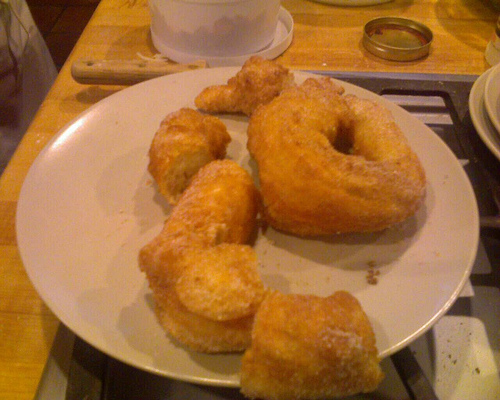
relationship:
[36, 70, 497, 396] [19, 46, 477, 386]
placemat under plate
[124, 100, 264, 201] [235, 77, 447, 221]
doughnut next to doughnut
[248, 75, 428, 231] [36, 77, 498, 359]
doughnut on a plate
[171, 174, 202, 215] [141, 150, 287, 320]
sugar on food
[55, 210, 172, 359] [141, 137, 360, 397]
plate under food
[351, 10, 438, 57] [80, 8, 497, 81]
lid on top of counter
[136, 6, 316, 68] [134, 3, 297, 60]
lid underneath container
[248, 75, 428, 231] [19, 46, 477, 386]
doughnut on top of plate